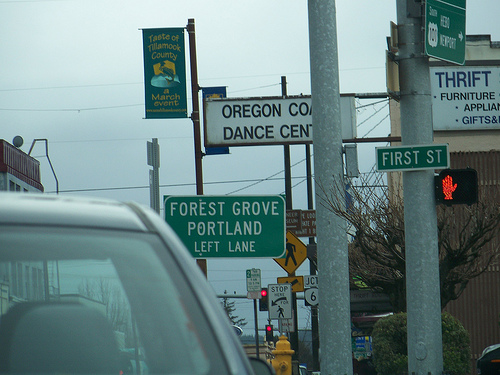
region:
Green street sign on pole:
[154, 186, 296, 267]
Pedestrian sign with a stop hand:
[433, 159, 488, 215]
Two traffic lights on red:
[251, 285, 276, 350]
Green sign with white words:
[154, 187, 292, 262]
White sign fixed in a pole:
[199, 90, 416, 151]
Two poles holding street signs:
[289, 0, 448, 368]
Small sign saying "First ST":
[365, 140, 459, 181]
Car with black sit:
[1, 184, 267, 373]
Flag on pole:
[130, 20, 188, 125]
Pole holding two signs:
[142, 16, 235, 291]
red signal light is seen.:
[242, 278, 282, 339]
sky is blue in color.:
[30, 31, 110, 66]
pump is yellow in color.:
[265, 325, 295, 370]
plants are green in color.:
[375, 315, 470, 355]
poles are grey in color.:
[315, 241, 445, 341]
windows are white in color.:
[6, 260, 51, 295]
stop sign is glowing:
[431, 171, 471, 206]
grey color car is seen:
[6, 190, 141, 257]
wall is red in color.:
[468, 292, 493, 342]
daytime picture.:
[22, 46, 492, 306]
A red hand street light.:
[437, 168, 482, 203]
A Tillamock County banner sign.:
[140, 23, 189, 121]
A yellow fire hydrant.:
[267, 335, 294, 373]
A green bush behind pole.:
[372, 313, 470, 373]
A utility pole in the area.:
[309, 70, 364, 373]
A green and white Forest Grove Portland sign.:
[166, 200, 287, 254]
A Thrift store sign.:
[429, 60, 499, 132]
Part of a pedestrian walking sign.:
[283, 232, 303, 272]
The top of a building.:
[0, 131, 65, 190]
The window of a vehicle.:
[0, 193, 262, 373]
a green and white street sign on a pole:
[366, 135, 457, 175]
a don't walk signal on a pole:
[428, 162, 488, 215]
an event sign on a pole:
[125, 7, 205, 124]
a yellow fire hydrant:
[262, 331, 300, 372]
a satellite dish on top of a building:
[8, 130, 28, 154]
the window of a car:
[1, 184, 259, 373]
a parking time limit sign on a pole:
[242, 266, 264, 303]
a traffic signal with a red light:
[261, 321, 278, 351]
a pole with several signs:
[370, 0, 460, 372]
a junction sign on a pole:
[300, 270, 320, 320]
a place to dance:
[196, 89, 363, 154]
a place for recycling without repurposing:
[424, 60, 499, 136]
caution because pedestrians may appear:
[267, 225, 312, 275]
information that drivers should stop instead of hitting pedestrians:
[262, 282, 291, 326]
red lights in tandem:
[254, 276, 274, 352]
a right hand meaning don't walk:
[420, 146, 490, 248]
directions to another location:
[152, 187, 292, 263]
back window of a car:
[0, 191, 249, 372]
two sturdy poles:
[303, 82, 450, 373]